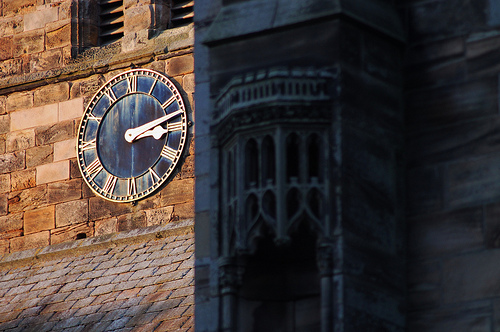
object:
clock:
[74, 68, 191, 204]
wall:
[0, 1, 213, 269]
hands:
[123, 108, 186, 143]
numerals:
[122, 72, 140, 94]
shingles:
[166, 284, 196, 298]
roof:
[1, 235, 195, 332]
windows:
[69, 0, 126, 59]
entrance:
[233, 225, 333, 330]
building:
[2, 0, 196, 332]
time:
[73, 68, 189, 205]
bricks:
[44, 267, 75, 281]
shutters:
[98, 25, 125, 37]